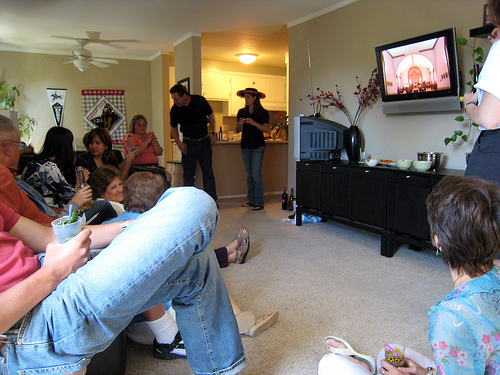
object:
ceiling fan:
[42, 37, 119, 71]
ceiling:
[0, 0, 198, 57]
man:
[166, 83, 221, 205]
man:
[0, 115, 63, 237]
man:
[0, 186, 248, 374]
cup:
[382, 340, 407, 367]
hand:
[41, 228, 92, 279]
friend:
[233, 87, 276, 211]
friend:
[169, 76, 218, 206]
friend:
[124, 114, 162, 175]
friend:
[72, 127, 126, 187]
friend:
[318, 175, 498, 374]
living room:
[0, 3, 500, 375]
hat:
[236, 87, 267, 99]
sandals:
[235, 234, 251, 262]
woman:
[318, 176, 500, 375]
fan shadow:
[53, 32, 140, 52]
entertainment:
[378, 39, 460, 112]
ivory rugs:
[125, 200, 447, 373]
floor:
[127, 202, 454, 374]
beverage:
[383, 342, 406, 373]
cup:
[46, 211, 90, 265]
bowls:
[412, 160, 432, 172]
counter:
[287, 158, 496, 261]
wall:
[283, 5, 499, 242]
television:
[373, 27, 466, 115]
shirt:
[418, 269, 500, 375]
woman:
[232, 87, 280, 210]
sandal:
[249, 310, 280, 338]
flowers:
[298, 96, 304, 101]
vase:
[342, 124, 364, 162]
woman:
[69, 127, 126, 192]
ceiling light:
[234, 38, 261, 67]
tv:
[293, 113, 351, 165]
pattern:
[438, 294, 484, 363]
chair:
[86, 341, 126, 375]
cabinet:
[295, 162, 467, 255]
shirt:
[236, 106, 270, 146]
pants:
[240, 140, 268, 206]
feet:
[241, 311, 281, 337]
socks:
[147, 315, 177, 343]